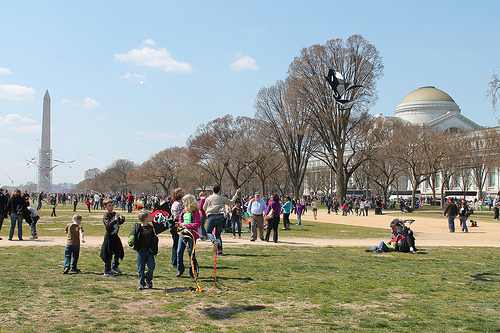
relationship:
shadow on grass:
[201, 297, 261, 317] [203, 261, 401, 328]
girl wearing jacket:
[171, 194, 202, 271] [174, 208, 204, 239]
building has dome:
[285, 85, 500, 204] [391, 85, 456, 108]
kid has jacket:
[100, 200, 124, 274] [101, 233, 125, 262]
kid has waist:
[100, 200, 124, 274] [104, 229, 125, 241]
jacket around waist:
[101, 233, 125, 262] [104, 229, 125, 241]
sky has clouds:
[4, 1, 500, 140] [115, 42, 261, 78]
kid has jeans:
[100, 200, 124, 274] [103, 252, 127, 271]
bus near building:
[440, 189, 483, 204] [285, 85, 500, 204]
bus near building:
[387, 188, 420, 204] [285, 85, 500, 204]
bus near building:
[345, 189, 370, 199] [285, 85, 500, 204]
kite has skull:
[151, 209, 177, 231] [153, 212, 165, 221]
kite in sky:
[26, 152, 58, 176] [4, 1, 500, 140]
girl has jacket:
[171, 194, 202, 271] [174, 209, 204, 232]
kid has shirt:
[66, 211, 86, 268] [64, 222, 85, 245]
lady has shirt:
[265, 195, 281, 241] [266, 202, 283, 219]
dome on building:
[391, 85, 456, 108] [285, 85, 500, 204]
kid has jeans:
[66, 211, 86, 268] [103, 252, 127, 271]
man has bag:
[244, 193, 267, 240] [248, 196, 256, 206]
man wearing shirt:
[244, 193, 267, 240] [248, 201, 266, 215]